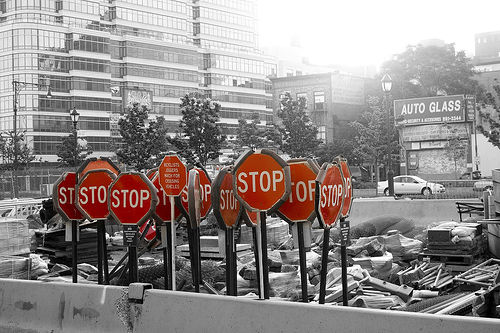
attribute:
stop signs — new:
[45, 149, 370, 239]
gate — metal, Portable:
[422, 177, 499, 204]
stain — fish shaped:
[71, 304, 100, 321]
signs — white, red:
[37, 154, 359, 240]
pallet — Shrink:
[1, 214, 37, 271]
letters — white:
[112, 190, 148, 208]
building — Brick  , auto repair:
[349, 34, 499, 176]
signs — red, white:
[26, 144, 375, 317]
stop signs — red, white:
[59, 137, 344, 261]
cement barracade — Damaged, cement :
[0, 275, 499, 330]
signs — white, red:
[45, 152, 363, 277]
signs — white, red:
[53, 152, 353, 224]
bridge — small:
[353, 315, 385, 330]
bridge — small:
[37, 244, 289, 329]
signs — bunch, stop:
[119, 149, 333, 254]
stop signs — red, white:
[46, 150, 353, 232]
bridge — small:
[377, 177, 488, 201]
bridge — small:
[19, 265, 495, 331]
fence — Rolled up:
[121, 253, 219, 287]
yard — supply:
[0, 0, 498, 329]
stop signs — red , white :
[42, 145, 359, 234]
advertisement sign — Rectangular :
[388, 99, 469, 126]